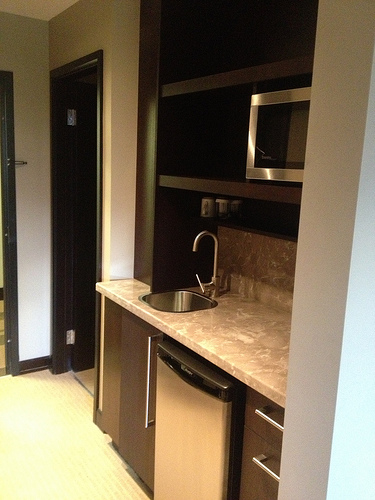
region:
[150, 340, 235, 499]
the dishwasher under the counter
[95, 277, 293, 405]
the counter top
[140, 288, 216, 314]
the small stainless steel sink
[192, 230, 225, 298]
the faucet above the sink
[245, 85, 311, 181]
the microwave on the shelf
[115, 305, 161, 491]
the cabinet door under the sink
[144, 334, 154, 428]
the handle to the cabinet door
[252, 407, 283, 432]
the handle for the top drawer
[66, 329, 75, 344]
the bottom door hinge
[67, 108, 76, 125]
the top door hinge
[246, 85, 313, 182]
a silver colored microwave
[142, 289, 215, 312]
a silver sink basin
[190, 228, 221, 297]
a silver sink faucet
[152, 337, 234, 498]
a silver colored dishwasher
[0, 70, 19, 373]
the edge of a doorway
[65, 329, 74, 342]
a silver door hinge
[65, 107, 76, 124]
a silver door hinge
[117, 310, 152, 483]
a wooden cabinet door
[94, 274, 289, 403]
a kitchen counter top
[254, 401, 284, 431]
a silver drawer handle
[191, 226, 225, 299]
The faucet for the sink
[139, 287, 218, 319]
The silver sink on the counter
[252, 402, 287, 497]
The silver handles to the drawers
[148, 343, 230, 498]
The dish washer in the counter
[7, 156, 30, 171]
The lock for the front door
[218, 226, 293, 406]
The white marble counter top with streaks in it.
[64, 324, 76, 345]
The metal hinges to the door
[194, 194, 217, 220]
an electical socket on the wall with a plug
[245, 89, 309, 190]
part of the micrwave sticking out on the shelf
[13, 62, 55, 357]
The white wall near the doors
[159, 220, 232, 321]
the faucet is silver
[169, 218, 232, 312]
the faucet is curved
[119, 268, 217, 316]
the sink is clean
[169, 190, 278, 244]
cups on the shelf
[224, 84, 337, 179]
microwave on the top shelf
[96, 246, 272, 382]
the counter top is beige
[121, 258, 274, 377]
the countertop is marble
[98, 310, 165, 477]
the cabinet is brown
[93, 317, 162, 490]
the cabinet is made of wood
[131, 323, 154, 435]
the handle is metal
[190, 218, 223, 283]
this is a tap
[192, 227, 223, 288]
the tap is metallic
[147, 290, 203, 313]
this is a sink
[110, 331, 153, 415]
this is a drawer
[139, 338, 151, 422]
this is the handle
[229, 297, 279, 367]
the stand is tiled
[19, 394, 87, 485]
this is the floor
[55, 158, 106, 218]
the door is open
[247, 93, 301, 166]
this is a microwave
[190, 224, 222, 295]
the tap is closed